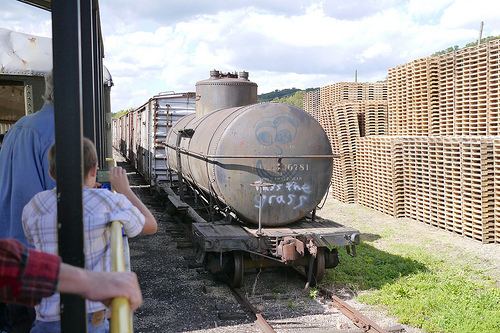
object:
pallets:
[330, 82, 351, 93]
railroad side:
[363, 244, 498, 291]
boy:
[20, 136, 158, 333]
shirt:
[20, 185, 145, 322]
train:
[109, 63, 357, 291]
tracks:
[221, 276, 388, 331]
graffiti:
[249, 111, 306, 183]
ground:
[112, 153, 498, 329]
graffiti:
[254, 180, 310, 210]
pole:
[48, 0, 87, 330]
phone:
[96, 169, 112, 182]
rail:
[106, 156, 131, 333]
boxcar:
[134, 92, 196, 184]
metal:
[198, 105, 336, 228]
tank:
[162, 69, 334, 222]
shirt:
[0, 238, 69, 304]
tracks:
[215, 274, 406, 331]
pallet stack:
[457, 199, 490, 240]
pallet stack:
[436, 47, 456, 65]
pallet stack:
[412, 108, 432, 127]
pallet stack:
[402, 193, 420, 217]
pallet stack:
[364, 101, 385, 114]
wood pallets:
[368, 124, 390, 138]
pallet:
[318, 102, 353, 115]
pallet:
[373, 136, 401, 156]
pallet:
[384, 69, 405, 82]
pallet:
[425, 46, 458, 66]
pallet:
[462, 49, 489, 67]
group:
[2, 65, 143, 332]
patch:
[383, 266, 499, 332]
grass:
[354, 247, 483, 325]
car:
[158, 67, 360, 289]